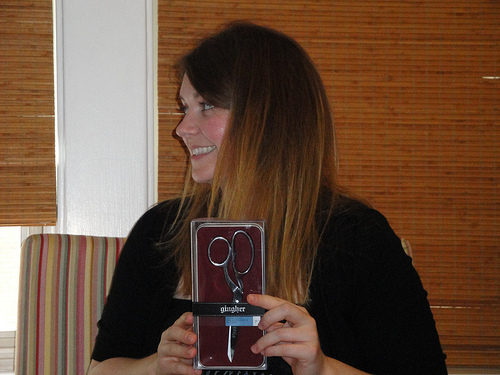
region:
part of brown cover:
[449, 75, 464, 105]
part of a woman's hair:
[268, 190, 280, 192]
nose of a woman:
[180, 115, 190, 127]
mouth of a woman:
[196, 137, 210, 152]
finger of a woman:
[271, 332, 279, 339]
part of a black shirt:
[352, 247, 358, 266]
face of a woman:
[178, 96, 214, 181]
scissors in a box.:
[187, 219, 273, 367]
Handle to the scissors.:
[196, 228, 258, 293]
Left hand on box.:
[241, 289, 324, 374]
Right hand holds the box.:
[144, 309, 205, 374]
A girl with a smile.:
[167, 19, 337, 199]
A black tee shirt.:
[91, 188, 448, 374]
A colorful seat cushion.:
[19, 236, 94, 373]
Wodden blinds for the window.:
[0, 5, 55, 225]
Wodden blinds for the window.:
[327, 0, 498, 193]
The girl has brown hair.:
[221, 43, 319, 205]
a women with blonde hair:
[115, 17, 407, 299]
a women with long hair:
[124, 6, 424, 333]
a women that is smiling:
[107, 15, 378, 260]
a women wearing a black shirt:
[89, 18, 429, 374]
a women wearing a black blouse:
[93, 10, 406, 368]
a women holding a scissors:
[76, 183, 369, 373]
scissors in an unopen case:
[154, 170, 365, 371]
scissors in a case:
[168, 199, 349, 374]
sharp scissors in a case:
[149, 185, 331, 372]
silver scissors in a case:
[128, 157, 340, 368]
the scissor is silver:
[135, 192, 315, 355]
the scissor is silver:
[138, 237, 248, 362]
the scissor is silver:
[189, 230, 304, 367]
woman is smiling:
[68, 17, 456, 373]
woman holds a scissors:
[179, 209, 291, 374]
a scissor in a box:
[182, 214, 276, 373]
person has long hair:
[103, 14, 413, 348]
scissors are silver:
[205, 226, 261, 362]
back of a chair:
[10, 220, 110, 371]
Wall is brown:
[337, 0, 492, 180]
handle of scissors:
[200, 225, 265, 280]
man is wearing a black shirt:
[75, 10, 457, 370]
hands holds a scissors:
[150, 205, 333, 371]